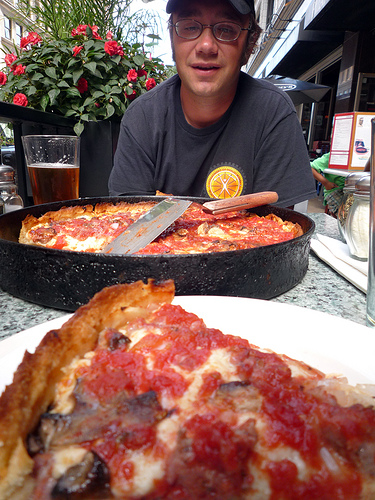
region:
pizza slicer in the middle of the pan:
[90, 181, 309, 257]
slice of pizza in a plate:
[2, 269, 365, 495]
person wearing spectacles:
[94, 6, 331, 235]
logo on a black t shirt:
[197, 158, 255, 208]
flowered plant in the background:
[3, 22, 158, 149]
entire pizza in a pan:
[10, 194, 315, 266]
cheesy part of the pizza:
[35, 307, 370, 491]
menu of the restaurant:
[328, 105, 373, 183]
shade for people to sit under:
[244, 67, 338, 108]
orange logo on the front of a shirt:
[206, 166, 243, 198]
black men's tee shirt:
[106, 70, 317, 205]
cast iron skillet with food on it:
[0, 194, 316, 311]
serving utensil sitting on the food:
[106, 191, 277, 253]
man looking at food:
[106, 3, 316, 204]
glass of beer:
[19, 133, 80, 206]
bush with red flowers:
[0, 26, 163, 131]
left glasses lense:
[176, 21, 199, 39]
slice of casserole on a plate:
[4, 278, 373, 498]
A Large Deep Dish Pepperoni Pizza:
[3, 184, 320, 307]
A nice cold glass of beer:
[16, 127, 87, 204]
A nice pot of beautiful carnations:
[0, 20, 161, 115]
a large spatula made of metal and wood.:
[95, 188, 290, 252]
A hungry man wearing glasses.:
[160, 3, 257, 108]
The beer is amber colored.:
[19, 131, 90, 209]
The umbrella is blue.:
[248, 60, 330, 103]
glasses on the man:
[148, 13, 233, 46]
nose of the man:
[192, 33, 217, 57]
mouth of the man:
[167, 53, 222, 78]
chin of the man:
[180, 83, 214, 102]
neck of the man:
[183, 92, 234, 104]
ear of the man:
[242, 24, 258, 50]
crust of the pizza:
[69, 301, 116, 332]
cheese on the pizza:
[215, 355, 241, 398]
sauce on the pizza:
[173, 434, 246, 485]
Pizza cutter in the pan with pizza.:
[121, 222, 171, 257]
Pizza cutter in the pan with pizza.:
[207, 211, 239, 236]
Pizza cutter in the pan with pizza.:
[32, 348, 81, 483]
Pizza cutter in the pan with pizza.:
[367, 398, 369, 493]